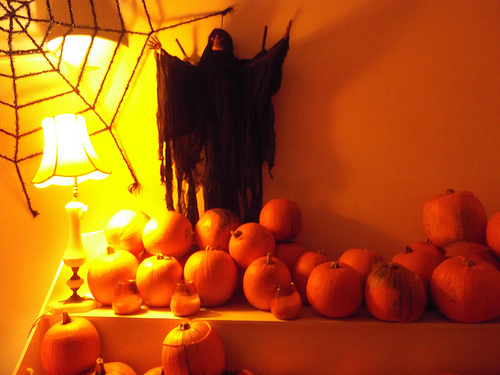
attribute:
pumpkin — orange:
[105, 203, 154, 255]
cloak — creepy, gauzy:
[143, 15, 293, 225]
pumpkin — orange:
[139, 200, 196, 260]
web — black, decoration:
[1, 1, 239, 219]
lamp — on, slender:
[26, 104, 114, 314]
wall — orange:
[1, 0, 499, 374]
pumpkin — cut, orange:
[155, 314, 227, 375]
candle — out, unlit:
[106, 273, 146, 318]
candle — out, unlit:
[165, 271, 205, 319]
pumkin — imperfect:
[365, 257, 431, 327]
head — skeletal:
[204, 19, 233, 57]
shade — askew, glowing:
[31, 97, 116, 194]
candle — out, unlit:
[269, 272, 309, 322]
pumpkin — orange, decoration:
[33, 307, 104, 374]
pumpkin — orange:
[81, 242, 140, 310]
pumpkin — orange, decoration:
[258, 190, 305, 248]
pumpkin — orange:
[223, 220, 281, 274]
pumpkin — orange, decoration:
[135, 248, 189, 315]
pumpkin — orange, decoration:
[178, 243, 239, 310]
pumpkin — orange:
[241, 250, 295, 314]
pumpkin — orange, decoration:
[304, 257, 363, 323]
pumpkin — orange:
[428, 252, 499, 324]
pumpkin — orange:
[337, 243, 385, 296]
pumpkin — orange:
[290, 245, 331, 308]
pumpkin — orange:
[380, 239, 447, 295]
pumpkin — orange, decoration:
[419, 172, 492, 251]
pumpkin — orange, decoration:
[192, 200, 245, 255]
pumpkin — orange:
[270, 235, 306, 280]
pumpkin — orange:
[481, 204, 499, 258]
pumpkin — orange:
[83, 349, 146, 374]